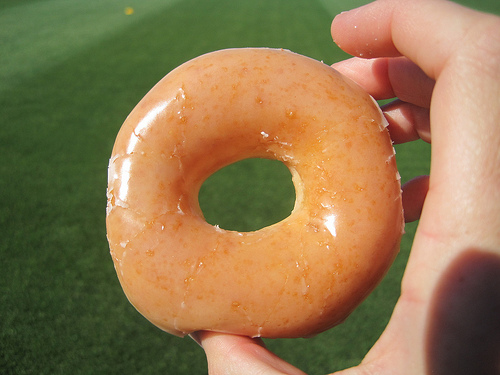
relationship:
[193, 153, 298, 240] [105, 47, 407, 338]
hole in cow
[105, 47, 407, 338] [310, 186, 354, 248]
cow with sugar coating